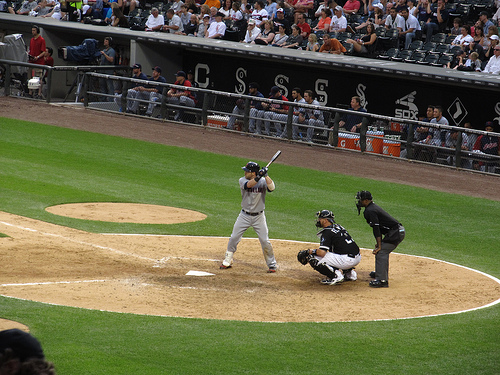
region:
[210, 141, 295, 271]
player holding bat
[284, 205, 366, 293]
baseball catcher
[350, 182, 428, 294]
baseball umpire wearing black uniform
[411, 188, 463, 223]
short dark and light green grass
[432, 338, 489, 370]
short dark and light green grass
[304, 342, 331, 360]
short dark and light green grass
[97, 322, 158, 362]
short dark and light green grass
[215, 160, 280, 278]
this is a batter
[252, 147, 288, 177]
this is a bat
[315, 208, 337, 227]
this is a helmet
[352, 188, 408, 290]
this is the umpire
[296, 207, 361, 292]
this is the catcher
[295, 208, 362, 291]
the catcher is bending down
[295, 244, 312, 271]
this is a black glove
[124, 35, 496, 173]
that's the player dugout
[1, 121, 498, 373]
this is some grass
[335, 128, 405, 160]
these are gatorade coolers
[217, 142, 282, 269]
player holding bat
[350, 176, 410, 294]
baseball umpire in black uniform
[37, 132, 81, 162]
short dark and light green grass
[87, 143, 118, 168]
short dark and light green grass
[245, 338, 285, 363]
short dark and light green grass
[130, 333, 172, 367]
short dark and light green grass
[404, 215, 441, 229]
short dark and light green grass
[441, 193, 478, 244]
short dark and light green grass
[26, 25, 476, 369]
A baseball field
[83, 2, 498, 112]
Fans in the stands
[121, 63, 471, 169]
Players in the dugout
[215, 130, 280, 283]
A batter in a grey uniform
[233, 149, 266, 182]
Batter wearing a black helmet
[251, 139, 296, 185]
A black and brown bat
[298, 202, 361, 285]
Catcher squatting behind batter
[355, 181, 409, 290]
Umpire behind the catcher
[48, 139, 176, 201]
Green turf on baseball field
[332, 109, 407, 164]
Orange coolers with white top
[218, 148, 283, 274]
baseball player is holding a bat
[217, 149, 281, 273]
baseball player waiting for a pitch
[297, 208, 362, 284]
catcher is crouched down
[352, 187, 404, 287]
umpire is bending over with his hands on his knees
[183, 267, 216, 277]
white home plate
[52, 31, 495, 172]
baseball team's dugout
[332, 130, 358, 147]
orange and white rectangular cooler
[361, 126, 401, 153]
two round orange and white coolers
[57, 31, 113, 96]
man is running a camera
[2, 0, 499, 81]
spectators sitting in the stands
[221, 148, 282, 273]
the batter is holding the bat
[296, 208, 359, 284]
the catcher is crouching down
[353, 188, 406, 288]
the umpire is bending over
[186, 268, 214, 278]
the home plate is white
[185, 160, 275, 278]
the player near the home plate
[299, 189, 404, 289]
the umpire is behind the catcher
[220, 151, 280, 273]
batter standing in the batter's box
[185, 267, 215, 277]
home plate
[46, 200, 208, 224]
dirt circle for the on deck batter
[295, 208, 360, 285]
catcher crouching behind home plate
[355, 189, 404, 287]
umpire crouching behind the catcher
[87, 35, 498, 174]
the dugout for the visiting team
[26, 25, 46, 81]
man in red operating a tv camera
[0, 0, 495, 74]
the stands with fans watching the game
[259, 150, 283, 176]
black wooden bat